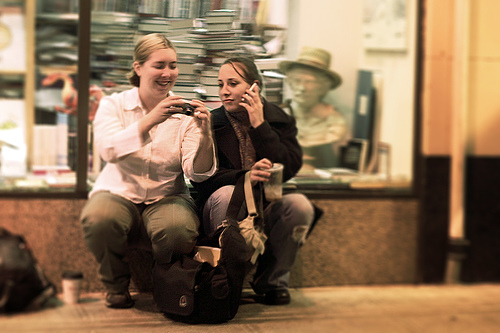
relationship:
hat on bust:
[279, 47, 342, 89] [280, 48, 346, 147]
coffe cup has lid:
[61, 270, 82, 303] [60, 271, 85, 280]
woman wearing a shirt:
[81, 32, 217, 307] [92, 88, 218, 206]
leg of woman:
[260, 192, 313, 289] [201, 57, 316, 303]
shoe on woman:
[252, 281, 293, 303] [201, 57, 316, 303]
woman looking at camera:
[201, 57, 316, 303] [180, 102, 195, 116]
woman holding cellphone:
[201, 57, 316, 303] [242, 84, 260, 103]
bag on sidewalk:
[160, 173, 249, 324] [1, 284, 499, 333]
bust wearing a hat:
[280, 48, 346, 147] [279, 47, 342, 89]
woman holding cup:
[201, 57, 316, 303] [261, 164, 284, 203]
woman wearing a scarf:
[201, 57, 316, 303] [220, 108, 258, 171]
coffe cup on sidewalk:
[61, 270, 82, 303] [1, 284, 499, 333]